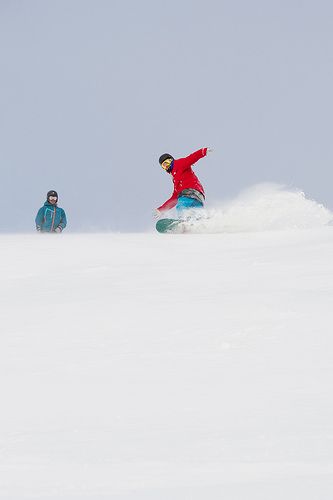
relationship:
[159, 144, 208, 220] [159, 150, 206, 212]
person has jacket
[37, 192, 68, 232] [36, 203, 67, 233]
person hs jacket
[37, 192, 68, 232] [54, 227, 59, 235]
person wearing glove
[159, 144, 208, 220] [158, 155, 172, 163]
person wearing cap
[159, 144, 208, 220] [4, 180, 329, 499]
person on top of snow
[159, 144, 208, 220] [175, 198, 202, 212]
person wearing pants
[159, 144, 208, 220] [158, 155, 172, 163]
person wear cap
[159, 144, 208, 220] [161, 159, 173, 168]
person wearing goggles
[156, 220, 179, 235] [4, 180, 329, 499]
snowboard spraying snow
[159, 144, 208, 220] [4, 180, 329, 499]
person standing on snow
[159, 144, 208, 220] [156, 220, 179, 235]
person riding snowboard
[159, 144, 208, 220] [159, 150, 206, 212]
person wearing jacket